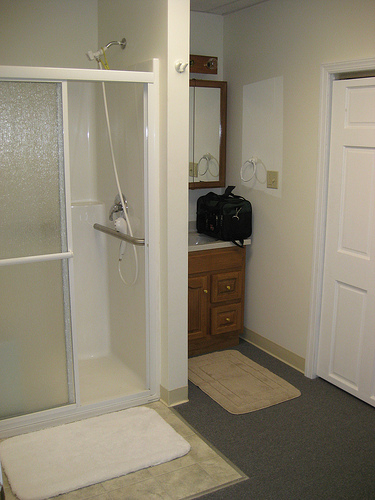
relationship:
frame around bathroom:
[0, 55, 373, 441] [0, 0, 375, 498]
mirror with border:
[188, 78, 228, 189] [220, 81, 227, 183]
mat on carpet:
[188, 344, 303, 414] [182, 336, 374, 498]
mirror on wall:
[188, 78, 228, 189] [190, 10, 226, 221]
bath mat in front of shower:
[0, 403, 194, 498] [0, 3, 169, 440]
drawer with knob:
[207, 268, 245, 303] [224, 283, 233, 291]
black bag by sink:
[196, 182, 253, 246] [186, 230, 213, 243]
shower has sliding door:
[0, 3, 169, 440] [1, 79, 79, 429]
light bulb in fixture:
[204, 57, 218, 69] [189, 53, 218, 76]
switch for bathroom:
[260, 161, 294, 190] [0, 0, 375, 498]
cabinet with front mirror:
[183, 71, 239, 196] [188, 78, 228, 189]